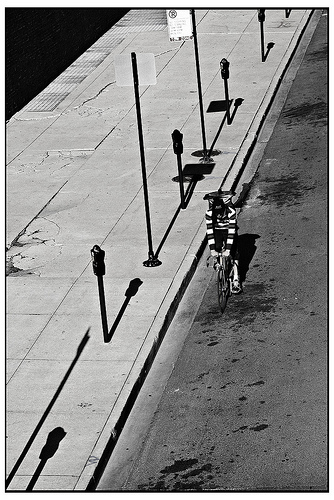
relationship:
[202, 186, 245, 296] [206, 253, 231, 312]
guy riding bike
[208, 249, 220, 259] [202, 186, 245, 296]
hand of guy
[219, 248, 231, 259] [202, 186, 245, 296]
hand of guy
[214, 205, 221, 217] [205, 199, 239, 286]
face on girl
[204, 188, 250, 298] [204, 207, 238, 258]
girl wearing shirt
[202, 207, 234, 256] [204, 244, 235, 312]
shirt on bike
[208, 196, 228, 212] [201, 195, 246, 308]
cap on cyclist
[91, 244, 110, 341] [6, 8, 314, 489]
parking meter on sidewalk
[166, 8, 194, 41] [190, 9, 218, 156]
sign on pole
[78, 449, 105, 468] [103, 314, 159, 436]
graffiti on curb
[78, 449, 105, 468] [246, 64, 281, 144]
graffiti on curb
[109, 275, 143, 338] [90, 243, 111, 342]
shadow from parking meter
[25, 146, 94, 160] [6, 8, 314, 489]
piece of sidewalk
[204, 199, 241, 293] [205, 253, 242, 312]
guy riding bike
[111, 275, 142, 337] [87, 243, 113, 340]
shadow on parking meter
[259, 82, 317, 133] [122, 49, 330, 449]
marks on road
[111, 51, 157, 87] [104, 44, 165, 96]
reverse side of traffic sign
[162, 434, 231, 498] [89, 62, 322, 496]
stains on a street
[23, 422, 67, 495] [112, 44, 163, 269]
shadow of a traffic sign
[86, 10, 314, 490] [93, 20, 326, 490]
curb of a street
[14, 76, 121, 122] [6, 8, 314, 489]
crack in sidewalk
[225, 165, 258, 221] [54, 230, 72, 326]
smudge on sidewalk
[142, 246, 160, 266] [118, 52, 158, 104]
base of a lamp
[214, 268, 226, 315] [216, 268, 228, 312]
tire of a tire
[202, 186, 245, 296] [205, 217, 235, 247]
guy wearing a striped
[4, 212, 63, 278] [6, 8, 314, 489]
cracked hole in sidewalk